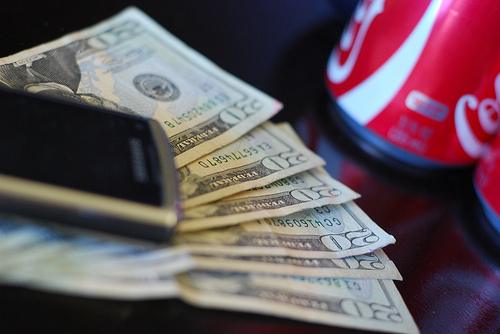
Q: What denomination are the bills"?
A: $20.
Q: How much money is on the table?
A: One hundred and twenty dollars.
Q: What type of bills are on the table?
A: Twenty dollar bills.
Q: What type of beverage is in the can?
A: Soda pop.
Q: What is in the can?
A: Coca-cola.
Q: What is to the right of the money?
A: A can of soda.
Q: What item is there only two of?
A: Soda can.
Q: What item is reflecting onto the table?
A: Soda can.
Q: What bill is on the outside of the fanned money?
A: A twenty dollar bill.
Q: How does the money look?
A: Green.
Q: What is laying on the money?
A: A pone.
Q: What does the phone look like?
A: Black and silver.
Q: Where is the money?
A: On a table.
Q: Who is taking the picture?
A: A photographer.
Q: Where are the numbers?
A: On the money.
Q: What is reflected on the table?
A: The soda cans.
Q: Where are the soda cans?
A: On the table.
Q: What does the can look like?
A: Red and white.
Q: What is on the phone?
A: White writing.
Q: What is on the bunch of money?
A: A cell phone.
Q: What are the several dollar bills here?
A: Twenty dollars.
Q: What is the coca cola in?
A: A can.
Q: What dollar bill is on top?
A: A twenty.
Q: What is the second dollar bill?
A: A twenty.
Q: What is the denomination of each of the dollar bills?
A: A twenty.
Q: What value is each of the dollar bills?
A: Twenty.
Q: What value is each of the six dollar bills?
A: Twenty.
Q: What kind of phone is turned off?
A: A cell phone.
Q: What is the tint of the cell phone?
A: Black and silver.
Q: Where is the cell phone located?
A: On a stack of money.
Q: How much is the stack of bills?
A: 20 dollar.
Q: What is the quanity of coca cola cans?
A: Two.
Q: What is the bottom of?
A: A soda can.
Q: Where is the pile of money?
A: On the table.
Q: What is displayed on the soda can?
A: White stripe.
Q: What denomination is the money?
A: Twenties.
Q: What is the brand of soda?
A: Coke.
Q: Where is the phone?
A: On top of the money.